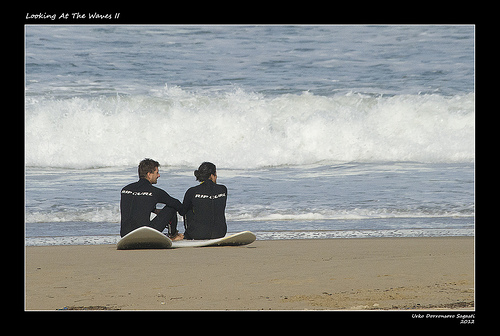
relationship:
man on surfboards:
[115, 157, 181, 241] [121, 237, 253, 253]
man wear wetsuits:
[115, 157, 181, 241] [119, 188, 225, 233]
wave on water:
[39, 90, 472, 170] [26, 31, 457, 91]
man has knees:
[115, 165, 180, 241] [156, 200, 174, 213]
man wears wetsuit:
[115, 165, 180, 241] [122, 186, 174, 237]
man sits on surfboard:
[115, 165, 180, 241] [117, 219, 183, 256]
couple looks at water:
[123, 154, 230, 256] [26, 31, 457, 91]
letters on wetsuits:
[122, 176, 232, 206] [119, 188, 225, 233]